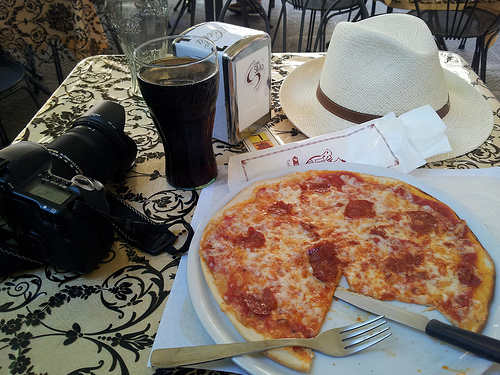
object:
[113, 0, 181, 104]
glass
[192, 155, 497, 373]
plate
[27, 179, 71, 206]
display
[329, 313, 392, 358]
silver prong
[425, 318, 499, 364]
handle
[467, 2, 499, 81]
chair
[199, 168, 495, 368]
pizza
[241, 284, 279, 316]
pepperoni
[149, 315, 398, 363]
fork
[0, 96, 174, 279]
camera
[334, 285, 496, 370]
knife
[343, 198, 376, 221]
pepperoni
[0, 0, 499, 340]
table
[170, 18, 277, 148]
napkin holder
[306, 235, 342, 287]
pepperoni